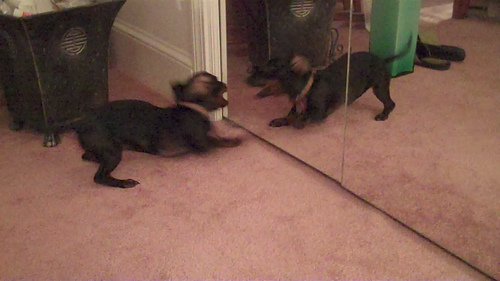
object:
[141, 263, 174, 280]
spot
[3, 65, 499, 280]
carpet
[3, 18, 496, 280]
floor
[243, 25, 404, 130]
reflection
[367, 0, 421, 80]
container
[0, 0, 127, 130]
container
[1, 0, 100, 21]
trash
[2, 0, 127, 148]
can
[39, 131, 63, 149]
foot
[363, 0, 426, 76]
column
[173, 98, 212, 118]
collar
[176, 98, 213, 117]
neck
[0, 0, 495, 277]
room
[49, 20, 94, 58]
circle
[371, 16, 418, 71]
post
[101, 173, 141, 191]
foot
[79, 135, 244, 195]
legs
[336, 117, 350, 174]
line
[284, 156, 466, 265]
lines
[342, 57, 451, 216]
lmirrors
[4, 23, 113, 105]
furniture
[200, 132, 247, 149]
leg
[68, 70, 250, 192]
dog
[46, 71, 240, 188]
coat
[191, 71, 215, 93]
ear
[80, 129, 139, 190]
leg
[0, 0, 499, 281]
wall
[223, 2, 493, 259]
mirror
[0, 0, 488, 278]
door